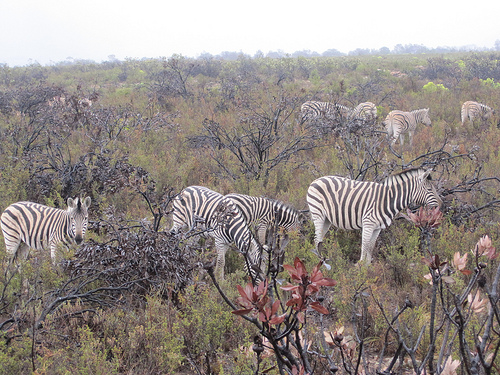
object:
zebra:
[305, 166, 443, 270]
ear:
[417, 165, 433, 181]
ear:
[65, 196, 75, 208]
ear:
[82, 195, 92, 207]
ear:
[425, 106, 429, 112]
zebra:
[384, 106, 431, 147]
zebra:
[165, 184, 271, 290]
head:
[240, 241, 275, 297]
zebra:
[210, 192, 305, 289]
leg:
[212, 239, 226, 285]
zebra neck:
[382, 170, 417, 224]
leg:
[311, 215, 325, 262]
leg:
[358, 228, 371, 264]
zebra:
[0, 195, 92, 266]